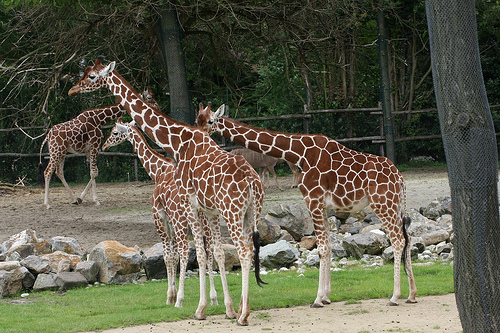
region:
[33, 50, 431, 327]
four giraffes in a pen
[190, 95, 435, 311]
giraffe has dark brown spots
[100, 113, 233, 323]
giraffe has light brown spots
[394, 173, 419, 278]
tail with a turf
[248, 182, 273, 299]
a big tail with black turf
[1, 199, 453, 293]
stones on side green grass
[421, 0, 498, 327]
a trunk near giraffes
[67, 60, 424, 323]
giraffes facing left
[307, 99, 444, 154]
a fence made of sticks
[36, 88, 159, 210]
giraffe walking to the right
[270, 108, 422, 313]
brown and beige giraffe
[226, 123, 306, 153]
long neck of a giraffe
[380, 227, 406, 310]
leg of a giraffe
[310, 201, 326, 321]
leg of a giraffe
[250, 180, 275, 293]
tail of a giraffe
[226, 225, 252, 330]
leg of a giraffe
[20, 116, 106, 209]
beige and brown giraffe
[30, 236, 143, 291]
rocks near tall giraffe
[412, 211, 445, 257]
rocks near a giraffe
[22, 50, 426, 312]
four giraffes standing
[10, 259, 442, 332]
grass three giraffes are standing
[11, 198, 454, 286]
piled up gray rocks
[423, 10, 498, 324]
dark grey tree trunk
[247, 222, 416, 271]
black tails of two giraffes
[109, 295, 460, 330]
pathway beside grass patch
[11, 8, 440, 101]
bare branches of trees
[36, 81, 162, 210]
giraffe walking in background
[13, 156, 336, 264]
dirt giraffe in background is walking on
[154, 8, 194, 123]
tree trunk beside background giraffe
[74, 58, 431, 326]
group of three girafes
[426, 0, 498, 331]
tree trunk covered with wire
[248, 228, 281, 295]
black hair at end of tail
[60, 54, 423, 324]
giraffes facing left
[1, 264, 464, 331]
green grass near rocks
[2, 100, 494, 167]
brown enclosure fence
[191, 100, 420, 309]
giraffe covered with brown patches of hair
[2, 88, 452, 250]
giraffe walking on bare soil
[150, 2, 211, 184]
large tree trunk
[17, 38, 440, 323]
a group of four giraffes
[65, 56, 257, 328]
a giraffe looking to his left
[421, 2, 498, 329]
a tree trunk with a fence around it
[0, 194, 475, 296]
a small wall of stones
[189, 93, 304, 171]
the long neck of a giraffe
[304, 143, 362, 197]
the brown spots of a giraffe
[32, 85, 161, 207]
a giraffe walking to the right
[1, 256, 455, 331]
a patch of bright green grass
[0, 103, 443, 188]
a wooden fence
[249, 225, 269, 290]
the black tail of a giraffe